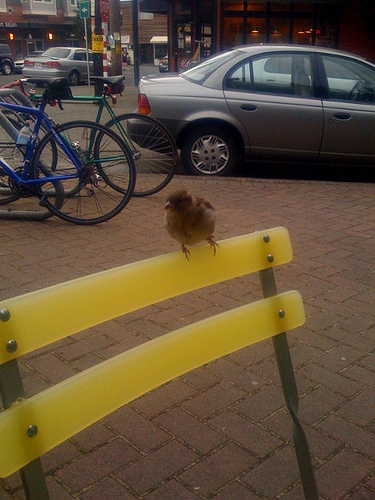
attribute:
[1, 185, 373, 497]
sidewalk — brick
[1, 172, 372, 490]
brick — red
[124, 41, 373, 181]
car — silver, parked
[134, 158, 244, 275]
bird — brown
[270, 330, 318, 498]
twist — metal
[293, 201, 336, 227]
brick — red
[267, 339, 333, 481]
black iron — twisted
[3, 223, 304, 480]
rail — twisted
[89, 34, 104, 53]
sign — yellow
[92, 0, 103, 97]
pole — black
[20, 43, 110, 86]
car — silver, parked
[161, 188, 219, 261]
bird — small, brown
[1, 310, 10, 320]
screw — silver 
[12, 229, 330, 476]
chair — yellow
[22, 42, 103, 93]
car — silver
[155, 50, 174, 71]
car — silver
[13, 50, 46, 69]
car — silver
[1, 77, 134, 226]
bike — blue , collapsing 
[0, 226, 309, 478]
chair — yellow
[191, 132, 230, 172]
hubcab — silver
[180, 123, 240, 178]
tire — black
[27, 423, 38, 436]
bolt — silver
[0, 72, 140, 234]
bicycle — bright blue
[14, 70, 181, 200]
bike — bright green, parked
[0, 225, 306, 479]
top — yellow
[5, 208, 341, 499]
chair — black